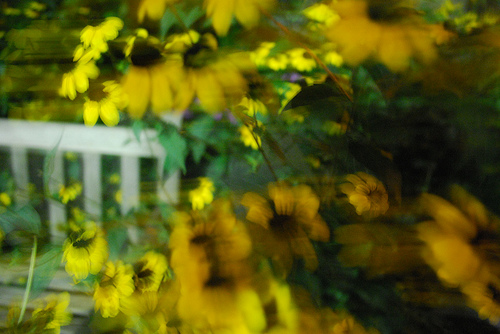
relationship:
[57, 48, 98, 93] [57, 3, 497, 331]
flower on bush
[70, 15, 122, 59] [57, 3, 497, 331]
flower on bush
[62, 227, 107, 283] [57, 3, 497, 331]
flower on bush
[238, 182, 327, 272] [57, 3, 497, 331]
flower on bush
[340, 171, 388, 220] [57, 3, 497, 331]
flower on bush